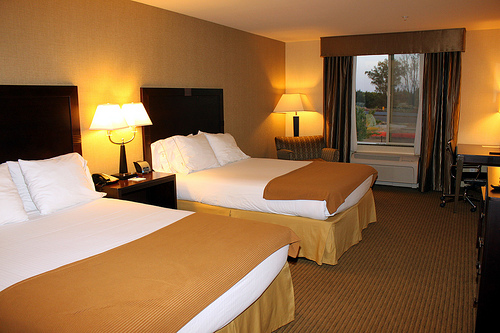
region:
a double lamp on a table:
[87, 102, 154, 162]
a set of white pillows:
[1, 159, 91, 199]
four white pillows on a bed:
[160, 134, 243, 166]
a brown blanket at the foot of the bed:
[12, 214, 295, 303]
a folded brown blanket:
[260, 167, 372, 205]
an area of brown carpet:
[353, 251, 464, 323]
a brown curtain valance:
[320, 29, 467, 52]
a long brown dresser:
[473, 195, 498, 331]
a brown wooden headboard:
[136, 82, 229, 134]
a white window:
[352, 54, 422, 154]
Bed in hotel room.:
[0, 153, 296, 330]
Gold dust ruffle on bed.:
[289, 196, 404, 264]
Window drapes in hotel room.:
[317, 38, 464, 167]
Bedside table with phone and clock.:
[93, 156, 180, 208]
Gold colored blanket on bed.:
[262, 163, 395, 208]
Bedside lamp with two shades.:
[92, 95, 140, 166]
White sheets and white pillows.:
[158, 133, 279, 189]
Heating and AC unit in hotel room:
[347, 137, 415, 183]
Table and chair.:
[435, 131, 497, 202]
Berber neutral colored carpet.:
[336, 242, 496, 324]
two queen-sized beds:
[0, 70, 382, 331]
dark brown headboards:
[0, 71, 235, 188]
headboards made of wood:
[0, 81, 235, 201]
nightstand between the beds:
[87, 96, 188, 218]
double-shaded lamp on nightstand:
[85, 92, 185, 205]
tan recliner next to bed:
[272, 121, 347, 167]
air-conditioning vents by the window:
[330, 140, 431, 188]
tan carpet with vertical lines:
[231, 160, 483, 330]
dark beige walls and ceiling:
[2, 2, 498, 191]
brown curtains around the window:
[315, 25, 466, 198]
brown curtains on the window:
[318, 28, 467, 197]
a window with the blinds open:
[352, 51, 422, 146]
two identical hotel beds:
[1, 81, 377, 331]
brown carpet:
[276, 173, 478, 330]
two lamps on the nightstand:
[92, 99, 152, 178]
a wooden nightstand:
[96, 166, 181, 211]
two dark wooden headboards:
[1, 81, 223, 173]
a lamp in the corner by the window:
[273, 90, 318, 136]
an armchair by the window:
[274, 132, 340, 162]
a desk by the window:
[448, 136, 498, 206]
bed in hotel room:
[141, 106, 384, 273]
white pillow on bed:
[16, 150, 107, 211]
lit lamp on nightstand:
[90, 94, 166, 186]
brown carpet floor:
[383, 216, 468, 320]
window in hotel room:
[346, 45, 424, 152]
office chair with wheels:
[442, 133, 487, 210]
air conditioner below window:
[342, 150, 424, 189]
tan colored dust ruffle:
[286, 185, 385, 271]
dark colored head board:
[136, 82, 236, 171]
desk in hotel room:
[451, 135, 499, 213]